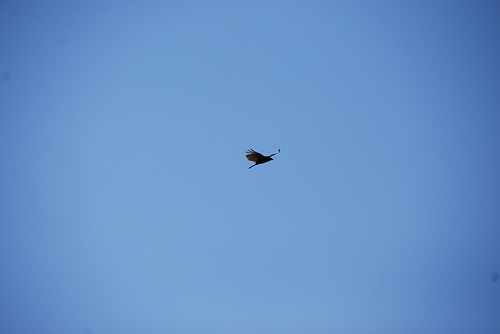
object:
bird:
[243, 146, 279, 168]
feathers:
[244, 148, 279, 169]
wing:
[244, 148, 265, 163]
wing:
[271, 149, 280, 158]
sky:
[6, 5, 498, 326]